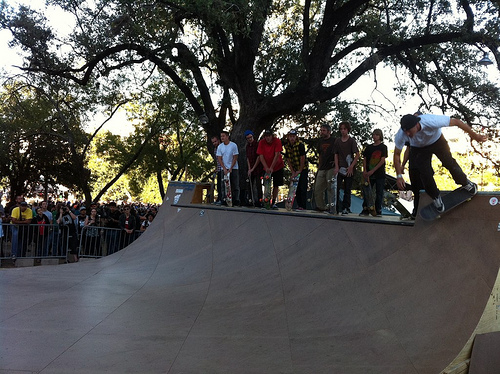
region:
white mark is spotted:
[489, 196, 495, 208]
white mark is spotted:
[487, 197, 495, 200]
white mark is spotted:
[486, 197, 497, 203]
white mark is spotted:
[485, 195, 496, 213]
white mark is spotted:
[488, 193, 495, 198]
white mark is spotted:
[481, 193, 496, 198]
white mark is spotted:
[488, 195, 498, 200]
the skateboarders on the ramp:
[205, 115, 460, 213]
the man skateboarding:
[392, 103, 481, 222]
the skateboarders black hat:
[397, 117, 419, 127]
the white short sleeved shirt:
[382, 110, 450, 150]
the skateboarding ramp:
[95, 181, 497, 371]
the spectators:
[9, 192, 139, 228]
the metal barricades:
[5, 220, 124, 255]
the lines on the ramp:
[40, 254, 351, 354]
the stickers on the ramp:
[167, 180, 206, 219]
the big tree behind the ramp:
[13, 0, 496, 154]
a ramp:
[159, 235, 267, 367]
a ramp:
[190, 280, 304, 350]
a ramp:
[181, 255, 263, 336]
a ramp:
[202, 240, 314, 372]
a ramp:
[214, 271, 282, 366]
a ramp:
[247, 267, 339, 371]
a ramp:
[157, 187, 311, 349]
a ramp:
[231, 261, 295, 349]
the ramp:
[137, 211, 321, 363]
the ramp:
[104, 174, 225, 324]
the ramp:
[194, 224, 257, 347]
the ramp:
[189, 262, 285, 368]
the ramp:
[168, 270, 221, 354]